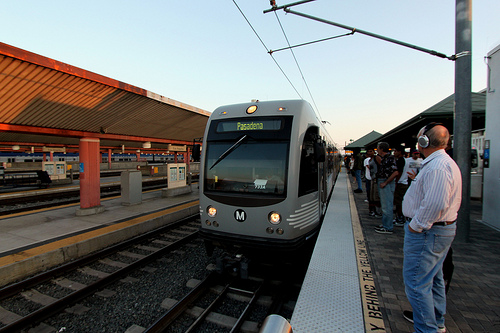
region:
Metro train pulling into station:
[188, 80, 323, 272]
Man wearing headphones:
[414, 118, 448, 157]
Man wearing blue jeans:
[400, 212, 449, 330]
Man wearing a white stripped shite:
[408, 153, 463, 224]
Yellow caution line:
[341, 185, 369, 331]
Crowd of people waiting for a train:
[356, 125, 414, 222]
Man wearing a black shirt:
[378, 152, 395, 184]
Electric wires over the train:
[264, 43, 334, 120]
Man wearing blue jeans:
[375, 172, 402, 235]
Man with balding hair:
[419, 128, 434, 151]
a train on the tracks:
[127, 93, 339, 332]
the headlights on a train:
[264, 210, 284, 225]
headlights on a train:
[202, 201, 225, 220]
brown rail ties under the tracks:
[3, 238, 298, 329]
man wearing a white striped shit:
[394, 120, 479, 332]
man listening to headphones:
[398, 118, 469, 331]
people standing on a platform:
[342, 120, 486, 331]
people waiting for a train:
[340, 120, 470, 322]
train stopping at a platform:
[192, 96, 353, 279]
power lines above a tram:
[227, 0, 349, 132]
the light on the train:
[267, 211, 281, 224]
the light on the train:
[206, 206, 217, 217]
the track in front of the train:
[120, 259, 285, 331]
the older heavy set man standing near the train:
[400, 124, 460, 332]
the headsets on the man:
[417, 120, 441, 147]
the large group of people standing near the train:
[340, 121, 455, 332]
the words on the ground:
[355, 233, 385, 332]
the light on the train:
[245, 103, 257, 115]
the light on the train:
[277, 105, 282, 110]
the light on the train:
[222, 109, 227, 115]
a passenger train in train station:
[163, 79, 351, 259]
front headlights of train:
[195, 200, 285, 230]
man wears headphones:
[390, 110, 460, 325]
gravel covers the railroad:
[20, 250, 263, 325]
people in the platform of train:
[358, 113, 455, 244]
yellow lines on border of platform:
[1, 191, 76, 257]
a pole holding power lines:
[235, 1, 477, 71]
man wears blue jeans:
[390, 110, 455, 331]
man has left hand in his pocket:
[396, 115, 468, 267]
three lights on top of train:
[213, 103, 285, 114]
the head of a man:
[411, 125, 466, 171]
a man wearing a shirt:
[407, 130, 493, 234]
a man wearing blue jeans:
[391, 200, 478, 327]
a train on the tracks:
[170, 66, 340, 241]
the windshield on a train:
[180, 125, 327, 217]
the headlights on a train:
[183, 203, 325, 245]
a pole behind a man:
[447, 14, 487, 282]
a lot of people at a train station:
[334, 78, 452, 240]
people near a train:
[345, 116, 462, 214]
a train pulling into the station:
[174, 34, 425, 300]